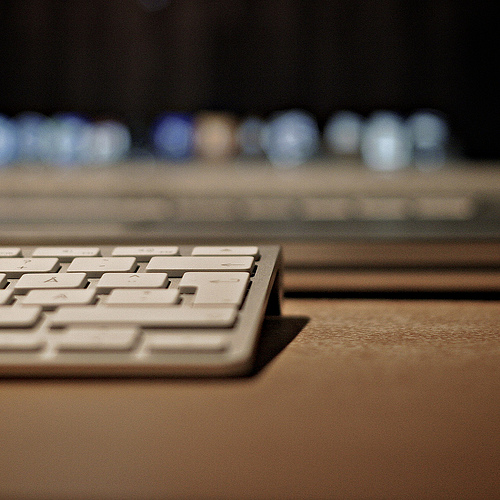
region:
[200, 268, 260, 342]
There is an enter key on this keyboard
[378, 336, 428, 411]
There is a brown surface on this desk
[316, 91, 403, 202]
There are blurry objects that are in the distance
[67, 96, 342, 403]
Jackson Mingus is the one who took this photo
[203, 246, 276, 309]
There is a key that is in the right corner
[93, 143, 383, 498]
This photo was taken in the city of Dayton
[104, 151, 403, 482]
This photo was taken in the state of Ohio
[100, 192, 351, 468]
This photo was taken by a professional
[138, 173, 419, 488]
This photo has a great amount of detail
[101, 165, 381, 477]
This photo will soon win an award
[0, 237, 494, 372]
This is a keyboard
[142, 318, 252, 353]
This is a keyboard key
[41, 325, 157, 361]
This is a keyboard key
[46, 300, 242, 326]
This is a keyboard key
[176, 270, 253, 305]
This is a keyboard key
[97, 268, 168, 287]
This is a keyboard key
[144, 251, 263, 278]
This is a keyboard key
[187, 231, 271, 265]
This is a keyboard key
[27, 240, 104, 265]
This is a keyboard key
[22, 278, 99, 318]
This is a keyboard key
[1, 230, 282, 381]
a computer keyboard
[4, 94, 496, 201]
the background out of focus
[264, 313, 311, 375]
the shadow of the keyboard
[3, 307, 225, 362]
some keys out of focus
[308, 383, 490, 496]
a brown surface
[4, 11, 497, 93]
a dark background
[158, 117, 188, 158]
a blue object out of focus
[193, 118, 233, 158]
an orange object out of focus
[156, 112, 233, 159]
a blue and orange objects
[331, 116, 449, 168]
three objects out of focus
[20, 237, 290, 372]
computer key board on brown surface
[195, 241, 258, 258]
computer key on the board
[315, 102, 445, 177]
blurry objects on a mantel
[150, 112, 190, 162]
blue blurry object on mantel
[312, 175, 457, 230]
front of tan brick mantel peace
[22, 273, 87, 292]
black cymbal on the key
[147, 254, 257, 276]
long key on the key board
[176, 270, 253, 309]
odd shape key on the key board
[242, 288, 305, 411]
shadow below the keyboard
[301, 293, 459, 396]
shinny section of the surface keyboard is on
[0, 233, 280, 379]
a keyboard on the table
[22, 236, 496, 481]
table is a brown color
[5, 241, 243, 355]
keyboard is a tan color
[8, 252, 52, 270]
the plus sign and question mark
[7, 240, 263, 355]
the keyboard is very clean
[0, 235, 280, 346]
the keys pop out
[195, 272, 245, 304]
the enter key that is a curved arrow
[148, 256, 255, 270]
a straight arrow key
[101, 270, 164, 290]
a key with different symbols